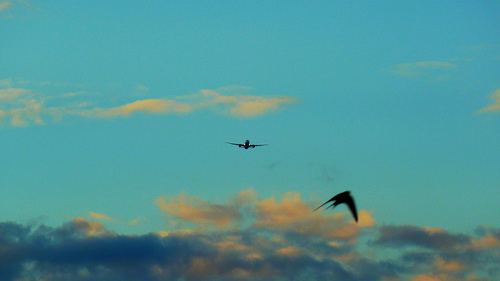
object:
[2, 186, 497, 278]
cloud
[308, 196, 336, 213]
wing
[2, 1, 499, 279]
sky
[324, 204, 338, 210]
tail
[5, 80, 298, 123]
cloud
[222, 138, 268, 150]
airplane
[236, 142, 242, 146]
part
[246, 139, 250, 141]
nose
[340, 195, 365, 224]
wing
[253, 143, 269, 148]
wing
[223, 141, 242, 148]
wing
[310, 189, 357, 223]
bird